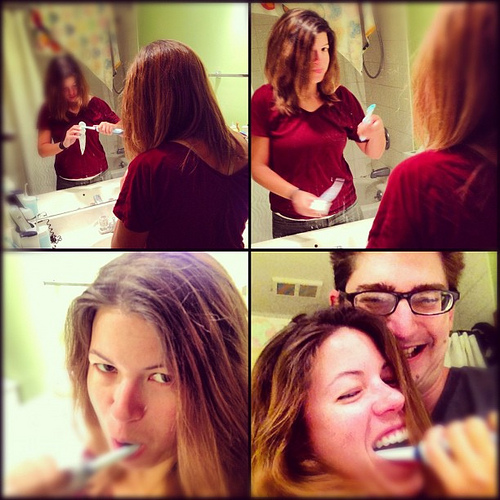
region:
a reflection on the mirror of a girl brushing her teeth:
[1, 1, 246, 246]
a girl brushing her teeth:
[251, 312, 496, 497]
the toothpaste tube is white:
[75, 120, 86, 155]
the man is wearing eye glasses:
[340, 281, 456, 314]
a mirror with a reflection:
[1, 1, 121, 187]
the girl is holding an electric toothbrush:
[84, 119, 125, 137]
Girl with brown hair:
[268, 7, 350, 107]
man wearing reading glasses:
[347, 275, 464, 324]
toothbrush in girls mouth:
[359, 428, 449, 474]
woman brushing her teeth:
[55, 423, 150, 463]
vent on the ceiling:
[268, 274, 328, 299]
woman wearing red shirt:
[114, 126, 219, 228]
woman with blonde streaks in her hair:
[253, 353, 308, 497]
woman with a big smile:
[358, 401, 428, 471]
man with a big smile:
[378, 329, 432, 369]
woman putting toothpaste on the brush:
[59, 110, 136, 155]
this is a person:
[20, 42, 127, 207]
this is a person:
[109, 27, 247, 257]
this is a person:
[251, 7, 376, 239]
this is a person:
[67, 247, 252, 499]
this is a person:
[256, 302, 421, 499]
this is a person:
[328, 240, 498, 472]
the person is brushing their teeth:
[52, 232, 252, 497]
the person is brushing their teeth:
[280, 297, 446, 484]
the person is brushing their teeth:
[66, 41, 255, 273]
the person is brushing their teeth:
[239, 12, 393, 237]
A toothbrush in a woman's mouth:
[377, 441, 470, 457]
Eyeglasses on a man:
[345, 283, 463, 318]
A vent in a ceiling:
[270, 275, 321, 299]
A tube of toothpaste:
[75, 121, 88, 154]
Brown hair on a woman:
[122, 37, 237, 164]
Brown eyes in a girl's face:
[89, 359, 177, 389]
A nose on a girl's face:
[369, 375, 403, 415]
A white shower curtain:
[0, 10, 64, 191]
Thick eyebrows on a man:
[355, 279, 450, 289]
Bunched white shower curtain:
[442, 331, 490, 370]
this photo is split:
[71, 63, 358, 471]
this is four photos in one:
[75, 31, 435, 431]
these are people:
[78, 97, 428, 477]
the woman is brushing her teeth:
[115, 163, 475, 485]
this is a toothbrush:
[40, 418, 178, 480]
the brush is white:
[51, 427, 206, 494]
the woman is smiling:
[310, 358, 490, 492]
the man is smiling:
[371, 287, 476, 378]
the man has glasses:
[361, 263, 481, 337]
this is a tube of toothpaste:
[42, 110, 137, 191]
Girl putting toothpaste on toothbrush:
[64, 99, 161, 209]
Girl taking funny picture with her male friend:
[263, 271, 493, 498]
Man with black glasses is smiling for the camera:
[330, 262, 495, 477]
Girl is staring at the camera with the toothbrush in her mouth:
[11, 275, 265, 498]